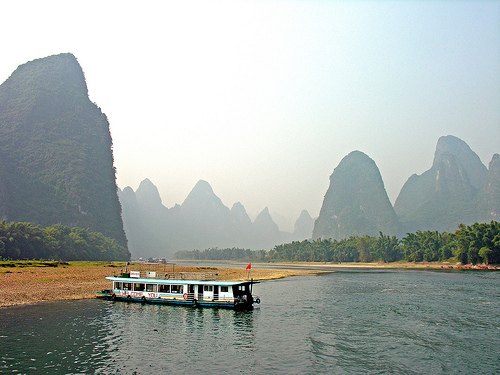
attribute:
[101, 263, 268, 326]
ferry boat — large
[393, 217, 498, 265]
trees — some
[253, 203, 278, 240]
mountain — several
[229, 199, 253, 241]
mountain — several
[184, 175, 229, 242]
mountain — several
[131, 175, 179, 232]
mountain — several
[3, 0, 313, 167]
clouds — white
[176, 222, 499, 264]
trees — green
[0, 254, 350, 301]
ground — brown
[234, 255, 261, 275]
flag — orange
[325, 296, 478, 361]
water — blue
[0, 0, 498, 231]
sky — blue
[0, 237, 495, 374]
water — calm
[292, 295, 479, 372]
waves — light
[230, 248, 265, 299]
flag — orange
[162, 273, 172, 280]
inflation device — circle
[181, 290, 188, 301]
inflation device — circle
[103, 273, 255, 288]
deck — top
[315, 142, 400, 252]
mountain — large, green, dome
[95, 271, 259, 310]
boat — white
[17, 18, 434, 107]
sky — bright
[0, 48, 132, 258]
mountain — tall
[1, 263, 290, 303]
side — both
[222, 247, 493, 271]
side — both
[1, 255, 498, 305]
shore — sandy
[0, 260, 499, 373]
water — blue